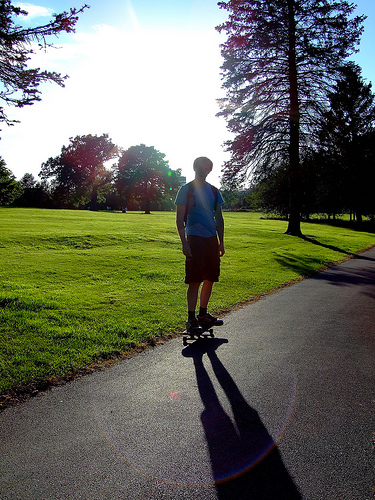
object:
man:
[172, 153, 231, 335]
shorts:
[181, 234, 221, 286]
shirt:
[171, 180, 226, 240]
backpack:
[180, 178, 222, 224]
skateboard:
[179, 314, 218, 343]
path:
[0, 243, 375, 497]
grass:
[0, 199, 375, 398]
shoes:
[185, 317, 203, 333]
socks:
[188, 309, 196, 320]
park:
[0, 0, 375, 500]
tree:
[216, 0, 364, 239]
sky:
[0, 0, 374, 198]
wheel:
[183, 336, 186, 341]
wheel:
[209, 329, 213, 334]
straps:
[183, 182, 192, 220]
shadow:
[185, 338, 307, 500]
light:
[83, 348, 301, 485]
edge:
[0, 243, 375, 420]